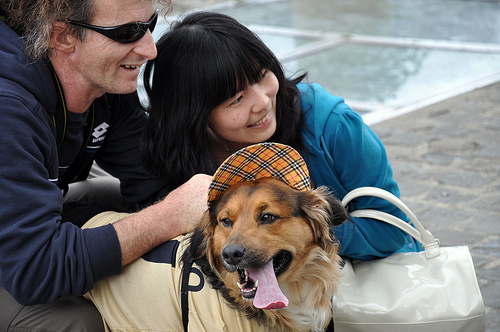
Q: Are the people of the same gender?
A: No, they are both male and female.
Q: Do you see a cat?
A: No, there are no cats.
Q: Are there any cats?
A: No, there are no cats.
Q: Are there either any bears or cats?
A: No, there are no cats or bears.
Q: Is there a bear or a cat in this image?
A: No, there are no cats or bears.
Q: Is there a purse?
A: Yes, there is a purse.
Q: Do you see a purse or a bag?
A: Yes, there is a purse.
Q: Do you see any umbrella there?
A: No, there are no umbrellas.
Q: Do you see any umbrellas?
A: No, there are no umbrellas.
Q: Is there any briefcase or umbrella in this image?
A: No, there are no umbrellas or briefcases.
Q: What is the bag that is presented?
A: The bag is a purse.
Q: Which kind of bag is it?
A: The bag is a purse.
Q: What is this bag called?
A: This is a purse.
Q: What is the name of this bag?
A: This is a purse.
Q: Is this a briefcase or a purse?
A: This is a purse.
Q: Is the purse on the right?
A: Yes, the purse is on the right of the image.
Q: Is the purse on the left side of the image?
A: No, the purse is on the right of the image.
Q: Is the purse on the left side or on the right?
A: The purse is on the right of the image.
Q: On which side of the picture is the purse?
A: The purse is on the right of the image.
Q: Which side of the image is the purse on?
A: The purse is on the right of the image.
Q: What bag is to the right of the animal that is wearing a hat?
A: The bag is a purse.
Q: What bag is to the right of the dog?
A: The bag is a purse.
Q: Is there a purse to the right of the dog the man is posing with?
A: Yes, there is a purse to the right of the dog.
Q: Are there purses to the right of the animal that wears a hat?
A: Yes, there is a purse to the right of the dog.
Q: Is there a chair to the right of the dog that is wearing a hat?
A: No, there is a purse to the right of the dog.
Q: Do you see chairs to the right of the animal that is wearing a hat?
A: No, there is a purse to the right of the dog.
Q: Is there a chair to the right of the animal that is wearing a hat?
A: No, there is a purse to the right of the dog.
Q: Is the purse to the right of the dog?
A: Yes, the purse is to the right of the dog.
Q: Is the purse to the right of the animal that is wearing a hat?
A: Yes, the purse is to the right of the dog.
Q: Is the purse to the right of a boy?
A: No, the purse is to the right of the dog.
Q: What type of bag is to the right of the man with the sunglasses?
A: The bag is a purse.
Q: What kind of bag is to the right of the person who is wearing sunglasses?
A: The bag is a purse.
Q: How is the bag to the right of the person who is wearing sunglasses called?
A: The bag is a purse.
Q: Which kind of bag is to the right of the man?
A: The bag is a purse.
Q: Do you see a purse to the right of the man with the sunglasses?
A: Yes, there is a purse to the right of the man.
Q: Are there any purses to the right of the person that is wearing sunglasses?
A: Yes, there is a purse to the right of the man.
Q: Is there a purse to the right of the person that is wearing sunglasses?
A: Yes, there is a purse to the right of the man.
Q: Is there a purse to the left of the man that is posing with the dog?
A: No, the purse is to the right of the man.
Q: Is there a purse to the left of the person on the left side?
A: No, the purse is to the right of the man.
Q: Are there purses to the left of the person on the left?
A: No, the purse is to the right of the man.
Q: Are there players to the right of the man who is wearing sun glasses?
A: No, there is a purse to the right of the man.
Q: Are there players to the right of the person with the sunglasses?
A: No, there is a purse to the right of the man.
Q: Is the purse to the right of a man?
A: Yes, the purse is to the right of a man.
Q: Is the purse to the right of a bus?
A: No, the purse is to the right of a man.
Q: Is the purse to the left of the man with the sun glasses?
A: No, the purse is to the right of the man.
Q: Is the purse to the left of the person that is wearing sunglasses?
A: No, the purse is to the right of the man.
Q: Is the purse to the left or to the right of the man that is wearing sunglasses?
A: The purse is to the right of the man.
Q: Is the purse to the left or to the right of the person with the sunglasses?
A: The purse is to the right of the man.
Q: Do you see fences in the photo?
A: No, there are no fences.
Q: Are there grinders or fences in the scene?
A: No, there are no fences or grinders.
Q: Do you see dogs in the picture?
A: Yes, there is a dog.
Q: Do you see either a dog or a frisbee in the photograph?
A: Yes, there is a dog.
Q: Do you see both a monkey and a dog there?
A: No, there is a dog but no monkeys.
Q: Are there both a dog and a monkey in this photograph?
A: No, there is a dog but no monkeys.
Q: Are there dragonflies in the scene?
A: No, there are no dragonflies.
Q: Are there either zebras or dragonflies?
A: No, there are no dragonflies or zebras.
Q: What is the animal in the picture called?
A: The animal is a dog.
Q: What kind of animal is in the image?
A: The animal is a dog.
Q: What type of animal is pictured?
A: The animal is a dog.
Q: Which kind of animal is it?
A: The animal is a dog.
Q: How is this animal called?
A: This is a dog.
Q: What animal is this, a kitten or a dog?
A: This is a dog.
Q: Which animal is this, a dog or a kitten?
A: This is a dog.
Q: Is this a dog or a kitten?
A: This is a dog.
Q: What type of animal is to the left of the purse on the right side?
A: The animal is a dog.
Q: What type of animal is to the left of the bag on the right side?
A: The animal is a dog.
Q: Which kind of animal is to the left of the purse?
A: The animal is a dog.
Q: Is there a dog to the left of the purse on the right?
A: Yes, there is a dog to the left of the purse.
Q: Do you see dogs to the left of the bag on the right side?
A: Yes, there is a dog to the left of the purse.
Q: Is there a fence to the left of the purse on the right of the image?
A: No, there is a dog to the left of the purse.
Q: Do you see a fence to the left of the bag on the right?
A: No, there is a dog to the left of the purse.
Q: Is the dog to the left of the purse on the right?
A: Yes, the dog is to the left of the purse.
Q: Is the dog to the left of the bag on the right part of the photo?
A: Yes, the dog is to the left of the purse.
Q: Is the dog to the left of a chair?
A: No, the dog is to the left of the purse.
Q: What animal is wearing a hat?
A: The dog is wearing a hat.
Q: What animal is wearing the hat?
A: The dog is wearing a hat.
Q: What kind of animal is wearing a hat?
A: The animal is a dog.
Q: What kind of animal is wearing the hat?
A: The animal is a dog.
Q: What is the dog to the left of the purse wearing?
A: The dog is wearing a hat.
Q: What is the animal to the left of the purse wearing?
A: The dog is wearing a hat.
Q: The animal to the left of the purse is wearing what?
A: The dog is wearing a hat.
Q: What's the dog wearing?
A: The dog is wearing a hat.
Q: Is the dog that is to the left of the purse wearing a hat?
A: Yes, the dog is wearing a hat.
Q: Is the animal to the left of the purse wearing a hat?
A: Yes, the dog is wearing a hat.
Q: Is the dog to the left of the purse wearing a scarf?
A: No, the dog is wearing a hat.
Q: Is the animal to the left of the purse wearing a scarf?
A: No, the dog is wearing a hat.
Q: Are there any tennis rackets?
A: No, there are no tennis rackets.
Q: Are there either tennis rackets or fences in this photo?
A: No, there are no tennis rackets or fences.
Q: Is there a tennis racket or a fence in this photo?
A: No, there are no rackets or fences.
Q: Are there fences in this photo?
A: No, there are no fences.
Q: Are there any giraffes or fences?
A: No, there are no fences or giraffes.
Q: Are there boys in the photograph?
A: No, there are no boys.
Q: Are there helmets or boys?
A: No, there are no boys or helmets.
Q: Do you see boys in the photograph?
A: No, there are no boys.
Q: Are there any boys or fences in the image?
A: No, there are no boys or fences.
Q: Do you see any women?
A: Yes, there is a woman.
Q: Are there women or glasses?
A: Yes, there is a woman.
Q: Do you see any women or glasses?
A: Yes, there is a woman.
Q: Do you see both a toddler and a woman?
A: No, there is a woman but no toddlers.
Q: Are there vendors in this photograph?
A: No, there are no vendors.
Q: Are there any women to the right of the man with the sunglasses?
A: Yes, there is a woman to the right of the man.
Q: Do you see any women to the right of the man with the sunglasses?
A: Yes, there is a woman to the right of the man.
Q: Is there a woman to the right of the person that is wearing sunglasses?
A: Yes, there is a woman to the right of the man.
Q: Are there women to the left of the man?
A: No, the woman is to the right of the man.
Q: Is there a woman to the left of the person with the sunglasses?
A: No, the woman is to the right of the man.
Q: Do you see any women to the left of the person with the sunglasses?
A: No, the woman is to the right of the man.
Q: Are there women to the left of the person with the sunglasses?
A: No, the woman is to the right of the man.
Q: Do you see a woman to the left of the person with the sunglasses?
A: No, the woman is to the right of the man.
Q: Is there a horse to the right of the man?
A: No, there is a woman to the right of the man.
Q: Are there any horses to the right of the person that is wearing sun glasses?
A: No, there is a woman to the right of the man.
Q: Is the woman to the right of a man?
A: Yes, the woman is to the right of a man.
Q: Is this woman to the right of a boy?
A: No, the woman is to the right of a man.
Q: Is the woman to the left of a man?
A: No, the woman is to the right of a man.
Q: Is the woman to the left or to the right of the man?
A: The woman is to the right of the man.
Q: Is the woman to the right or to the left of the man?
A: The woman is to the right of the man.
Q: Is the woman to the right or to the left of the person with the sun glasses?
A: The woman is to the right of the man.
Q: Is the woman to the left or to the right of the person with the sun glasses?
A: The woman is to the right of the man.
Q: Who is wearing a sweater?
A: The woman is wearing a sweater.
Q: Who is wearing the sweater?
A: The woman is wearing a sweater.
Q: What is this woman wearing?
A: The woman is wearing a sweater.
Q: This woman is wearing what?
A: The woman is wearing a sweater.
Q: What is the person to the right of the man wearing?
A: The woman is wearing a sweater.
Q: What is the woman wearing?
A: The woman is wearing a sweater.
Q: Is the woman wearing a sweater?
A: Yes, the woman is wearing a sweater.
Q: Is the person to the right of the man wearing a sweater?
A: Yes, the woman is wearing a sweater.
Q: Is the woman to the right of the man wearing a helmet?
A: No, the woman is wearing a sweater.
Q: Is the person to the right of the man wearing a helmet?
A: No, the woman is wearing a sweater.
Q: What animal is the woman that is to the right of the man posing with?
A: The woman is posing with the dog.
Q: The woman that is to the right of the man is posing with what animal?
A: The woman is posing with the dog.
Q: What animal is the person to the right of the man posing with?
A: The woman is posing with the dog.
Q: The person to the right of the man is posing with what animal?
A: The woman is posing with the dog.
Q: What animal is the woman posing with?
A: The woman is posing with the dog.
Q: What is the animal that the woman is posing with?
A: The animal is a dog.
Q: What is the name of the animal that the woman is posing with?
A: The animal is a dog.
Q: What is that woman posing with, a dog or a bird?
A: The woman is posing with a dog.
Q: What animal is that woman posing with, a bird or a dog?
A: The woman is posing with a dog.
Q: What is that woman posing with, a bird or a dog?
A: The woman is posing with a dog.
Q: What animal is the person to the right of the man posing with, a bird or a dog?
A: The woman is posing with a dog.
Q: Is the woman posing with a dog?
A: Yes, the woman is posing with a dog.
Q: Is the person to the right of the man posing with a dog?
A: Yes, the woman is posing with a dog.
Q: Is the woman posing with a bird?
A: No, the woman is posing with a dog.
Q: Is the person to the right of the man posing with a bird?
A: No, the woman is posing with a dog.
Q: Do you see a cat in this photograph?
A: No, there are no cats.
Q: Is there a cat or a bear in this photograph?
A: No, there are no cats or bears.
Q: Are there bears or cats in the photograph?
A: No, there are no cats or bears.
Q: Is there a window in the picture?
A: Yes, there is a window.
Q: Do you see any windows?
A: Yes, there is a window.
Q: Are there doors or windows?
A: Yes, there is a window.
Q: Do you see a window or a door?
A: Yes, there is a window.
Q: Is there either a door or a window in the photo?
A: Yes, there is a window.